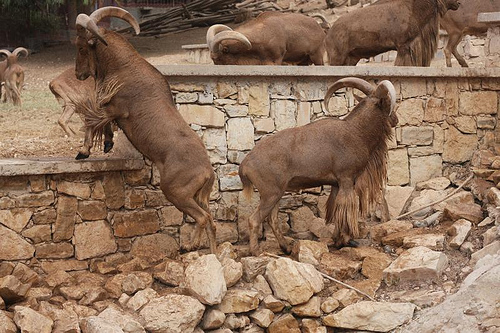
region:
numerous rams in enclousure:
[18, 9, 494, 240]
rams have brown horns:
[79, 13, 149, 53]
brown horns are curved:
[77, 2, 133, 49]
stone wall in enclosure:
[133, 77, 498, 258]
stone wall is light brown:
[198, 105, 456, 249]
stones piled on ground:
[9, 225, 381, 322]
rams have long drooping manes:
[317, 143, 394, 259]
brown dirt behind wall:
[3, 32, 188, 164]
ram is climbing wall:
[70, 13, 268, 283]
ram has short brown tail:
[231, 159, 271, 207]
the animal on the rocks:
[238, 75, 399, 257]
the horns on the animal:
[320, 76, 396, 124]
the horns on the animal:
[76, 6, 140, 43]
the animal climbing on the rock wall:
[72, 5, 218, 253]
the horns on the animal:
[205, 23, 254, 57]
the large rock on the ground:
[264, 257, 326, 304]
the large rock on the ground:
[384, 245, 447, 284]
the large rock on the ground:
[188, 255, 225, 305]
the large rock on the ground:
[138, 295, 205, 331]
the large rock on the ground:
[321, 302, 416, 331]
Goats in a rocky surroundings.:
[3, 2, 494, 327]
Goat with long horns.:
[320, 73, 396, 118]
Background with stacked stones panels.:
[135, 5, 207, 35]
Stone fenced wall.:
[5, 158, 150, 299]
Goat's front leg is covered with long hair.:
[330, 185, 361, 250]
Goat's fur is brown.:
[73, 25, 219, 251]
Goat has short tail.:
[238, 167, 255, 198]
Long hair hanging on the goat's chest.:
[354, 124, 396, 216]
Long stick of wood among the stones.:
[391, 170, 478, 220]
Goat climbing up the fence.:
[71, 4, 219, 264]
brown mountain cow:
[231, 70, 415, 241]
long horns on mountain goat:
[313, 68, 409, 120]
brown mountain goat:
[71, 8, 226, 243]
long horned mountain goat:
[61, 10, 228, 241]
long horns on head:
[70, 4, 146, 43]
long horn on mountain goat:
[205, 8, 340, 71]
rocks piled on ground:
[47, 204, 487, 331]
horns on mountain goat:
[0, 29, 33, 116]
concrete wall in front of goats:
[153, 66, 498, 224]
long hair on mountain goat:
[338, 147, 394, 237]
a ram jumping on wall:
[66, 5, 220, 251]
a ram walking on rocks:
[234, 73, 398, 255]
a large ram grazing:
[202, 4, 329, 68]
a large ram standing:
[323, 0, 461, 65]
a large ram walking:
[0, 44, 32, 105]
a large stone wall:
[0, 65, 497, 277]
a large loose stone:
[265, 253, 322, 303]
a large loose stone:
[183, 253, 228, 305]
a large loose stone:
[140, 293, 205, 331]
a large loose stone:
[323, 300, 415, 331]